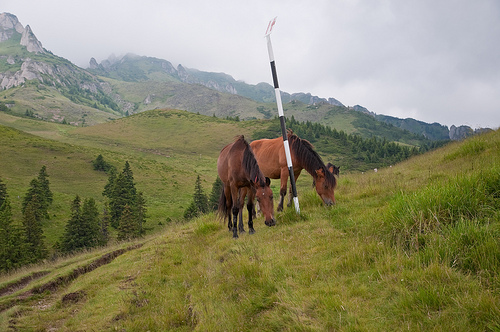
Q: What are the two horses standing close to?
A: A pole.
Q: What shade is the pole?
A: Black and white.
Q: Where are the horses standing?
A: On a hill.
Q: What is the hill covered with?
A: Grass.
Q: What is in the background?
A: A rocky mountain.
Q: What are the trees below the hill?
A: Pine trees.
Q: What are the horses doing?
A: Eating grass.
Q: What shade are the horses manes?
A: Black.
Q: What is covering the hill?
A: Green grass.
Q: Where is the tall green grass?
A: On the hill.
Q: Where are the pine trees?
A: On the hill behind the horses.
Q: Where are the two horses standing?
A: Next to each other.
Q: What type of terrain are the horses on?
A: A hill.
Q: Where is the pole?
A: Between the horses.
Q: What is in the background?
A: Mountains.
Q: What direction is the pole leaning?
A: Left.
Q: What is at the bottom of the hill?
A: Trees.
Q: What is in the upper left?
A: Mountains.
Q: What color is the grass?
A: Green.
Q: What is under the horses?
A: Grass.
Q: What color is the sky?
A: Gray.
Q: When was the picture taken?
A: Daytime.